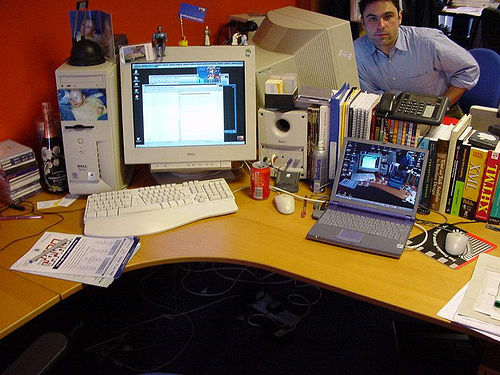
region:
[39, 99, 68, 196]
wine bottle on computer desk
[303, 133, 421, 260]
laptop sitting on the desk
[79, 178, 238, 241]
keyboard sitting on the computer desk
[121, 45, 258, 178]
computer monitor sitting on computer desk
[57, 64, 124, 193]
cpu tower sitting on the desk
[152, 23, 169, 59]
toy sitting on top of monitor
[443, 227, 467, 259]
mouse sitting on top of mousepad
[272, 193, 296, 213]
mouse sitting on top of desk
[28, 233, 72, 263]
pen sitting on top of desk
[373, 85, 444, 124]
telephone sitting on top of books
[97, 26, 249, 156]
white monitor on desk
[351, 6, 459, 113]
man sits behind books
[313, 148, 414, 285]
grey laptop on desk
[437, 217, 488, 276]
white mouse on mousepad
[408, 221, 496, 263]
red black and white mousepad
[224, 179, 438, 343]
brown and wooden desk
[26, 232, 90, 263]
pen on stack of paper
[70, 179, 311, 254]
white keyboard on desk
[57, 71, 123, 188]
white tower on desk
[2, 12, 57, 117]
orange wall behind computer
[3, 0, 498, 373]
two office spaces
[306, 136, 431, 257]
a gray laptop on a desk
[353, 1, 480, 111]
a man sitting at his computer desk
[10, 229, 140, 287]
papers on a desk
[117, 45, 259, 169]
a computer monitor on a desk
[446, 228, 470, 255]
a gray wired mouse on a mouse pad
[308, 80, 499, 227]
a stack of folders, binders and books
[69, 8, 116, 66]
a picture on top of a computer tower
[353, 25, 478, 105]
man wearing a blue button-down shirt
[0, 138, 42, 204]
a stack of CDs on a desk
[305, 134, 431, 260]
small silver laptop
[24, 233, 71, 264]
grey and blue pen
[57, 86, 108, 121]
picture of baby on cpu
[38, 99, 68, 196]
unopened bottle of champagne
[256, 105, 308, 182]
sub-woofer on desk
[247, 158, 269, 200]
small can of cola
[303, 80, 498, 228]
row of technical books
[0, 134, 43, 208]
small stack of computer discs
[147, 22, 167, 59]
robocop figurine on monitor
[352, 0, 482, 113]
man in blue, long sleeve shirt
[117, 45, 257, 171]
white big backed monitor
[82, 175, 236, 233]
white desk top keyboard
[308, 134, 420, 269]
silver laptop computer on screen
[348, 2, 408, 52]
man with brown hair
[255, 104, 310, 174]
sub woofer sound booster for speakers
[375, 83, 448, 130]
black desk corded phone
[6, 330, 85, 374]
black armrest on chair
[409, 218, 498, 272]
black, red, and white mousepad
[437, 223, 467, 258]
white desk top computer mouse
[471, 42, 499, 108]
blue backrest on chair